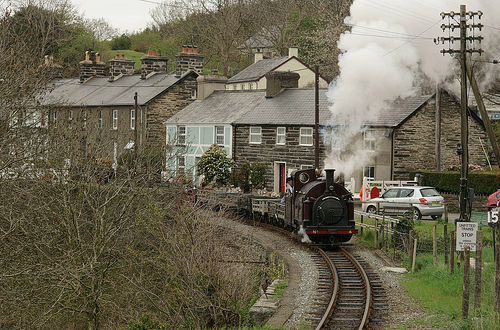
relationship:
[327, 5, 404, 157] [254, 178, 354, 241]
smoke billowing from train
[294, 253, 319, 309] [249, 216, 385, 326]
rocks by tracks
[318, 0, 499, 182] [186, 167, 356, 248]
smoke coming from train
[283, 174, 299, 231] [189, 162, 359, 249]
someone standing on train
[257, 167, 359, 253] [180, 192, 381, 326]
train on tracks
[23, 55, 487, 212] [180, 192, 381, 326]
houses next to tracks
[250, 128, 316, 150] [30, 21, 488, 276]
windows on side buildings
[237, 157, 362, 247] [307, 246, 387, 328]
train on tracks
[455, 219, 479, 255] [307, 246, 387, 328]
white sign by tracks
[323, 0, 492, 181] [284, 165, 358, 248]
steam on train engine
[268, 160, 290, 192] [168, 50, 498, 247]
door on house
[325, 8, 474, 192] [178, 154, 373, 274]
cloud coming out of train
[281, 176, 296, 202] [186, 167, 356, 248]
person on train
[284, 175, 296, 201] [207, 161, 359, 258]
engineer on train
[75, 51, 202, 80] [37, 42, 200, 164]
chimneys on houses